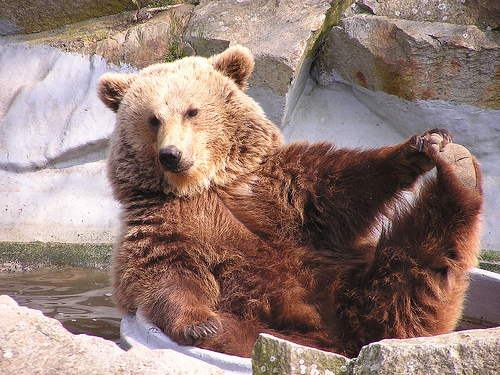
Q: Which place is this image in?
A: It is at the swimming pool.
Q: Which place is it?
A: It is a swimming pool.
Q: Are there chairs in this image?
A: No, there are no chairs.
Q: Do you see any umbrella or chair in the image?
A: No, there are no chairs or umbrellas.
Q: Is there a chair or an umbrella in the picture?
A: No, there are no chairs or umbrellas.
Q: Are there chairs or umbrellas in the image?
A: No, there are no chairs or umbrellas.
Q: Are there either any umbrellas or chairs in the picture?
A: No, there are no chairs or umbrellas.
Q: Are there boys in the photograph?
A: No, there are no boys.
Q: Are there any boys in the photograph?
A: No, there are no boys.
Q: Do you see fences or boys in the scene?
A: No, there are no boys or fences.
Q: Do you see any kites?
A: No, there are no kites.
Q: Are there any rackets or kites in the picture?
A: No, there are no kites or rackets.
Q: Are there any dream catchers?
A: No, there are no dream catchers.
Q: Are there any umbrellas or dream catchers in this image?
A: No, there are no dream catchers or umbrellas.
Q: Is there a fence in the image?
A: No, there are no fences.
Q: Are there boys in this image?
A: No, there are no boys.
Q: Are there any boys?
A: No, there are no boys.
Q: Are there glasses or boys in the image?
A: No, there are no boys or glasses.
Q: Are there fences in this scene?
A: No, there are no fences.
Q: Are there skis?
A: No, there are no skis.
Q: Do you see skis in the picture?
A: No, there are no skis.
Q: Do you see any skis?
A: No, there are no skis.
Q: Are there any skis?
A: No, there are no skis.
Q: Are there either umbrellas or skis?
A: No, there are no skis or umbrellas.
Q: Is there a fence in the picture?
A: No, there are no fences.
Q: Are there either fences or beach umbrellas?
A: No, there are no fences or beach umbrellas.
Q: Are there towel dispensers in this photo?
A: No, there are no towel dispensers.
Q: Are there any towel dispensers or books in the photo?
A: No, there are no towel dispensers or books.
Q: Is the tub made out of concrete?
A: Yes, the tub is made of concrete.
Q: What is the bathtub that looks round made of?
A: The bathtub is made of cement.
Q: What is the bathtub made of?
A: The bathtub is made of concrete.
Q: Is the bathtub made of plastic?
A: No, the bathtub is made of cement.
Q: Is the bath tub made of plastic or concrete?
A: The bath tub is made of concrete.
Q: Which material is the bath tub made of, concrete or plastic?
A: The bath tub is made of concrete.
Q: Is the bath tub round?
A: Yes, the bath tub is round.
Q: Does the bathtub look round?
A: Yes, the bathtub is round.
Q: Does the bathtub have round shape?
A: Yes, the bathtub is round.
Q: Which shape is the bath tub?
A: The bath tub is round.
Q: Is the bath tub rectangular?
A: No, the bath tub is round.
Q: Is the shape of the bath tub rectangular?
A: No, the bath tub is round.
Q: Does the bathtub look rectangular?
A: No, the bathtub is round.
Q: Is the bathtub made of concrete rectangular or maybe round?
A: The bath tub is round.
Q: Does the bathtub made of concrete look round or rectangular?
A: The bath tub is round.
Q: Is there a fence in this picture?
A: No, there are no fences.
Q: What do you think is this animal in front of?
A: The animal is in front of the water.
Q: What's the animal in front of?
A: The animal is in front of the water.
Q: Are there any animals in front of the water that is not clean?
A: Yes, there is an animal in front of the water.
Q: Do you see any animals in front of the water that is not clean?
A: Yes, there is an animal in front of the water.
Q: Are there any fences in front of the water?
A: No, there is an animal in front of the water.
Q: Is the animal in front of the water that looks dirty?
A: Yes, the animal is in front of the water.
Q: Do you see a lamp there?
A: No, there are no lamps.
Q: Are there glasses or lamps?
A: No, there are no lamps or glasses.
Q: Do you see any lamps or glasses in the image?
A: No, there are no lamps or glasses.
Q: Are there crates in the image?
A: No, there are no crates.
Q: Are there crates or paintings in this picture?
A: No, there are no crates or paintings.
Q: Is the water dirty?
A: Yes, the water is dirty.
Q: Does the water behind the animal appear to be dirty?
A: Yes, the water is dirty.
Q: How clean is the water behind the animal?
A: The water is dirty.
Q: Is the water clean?
A: No, the water is dirty.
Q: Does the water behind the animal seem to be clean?
A: No, the water is dirty.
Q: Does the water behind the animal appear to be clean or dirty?
A: The water is dirty.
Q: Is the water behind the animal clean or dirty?
A: The water is dirty.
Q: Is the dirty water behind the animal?
A: Yes, the water is behind the animal.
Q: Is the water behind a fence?
A: No, the water is behind the animal.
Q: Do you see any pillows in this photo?
A: No, there are no pillows.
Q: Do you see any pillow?
A: No, there are no pillows.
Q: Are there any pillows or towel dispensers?
A: No, there are no pillows or towel dispensers.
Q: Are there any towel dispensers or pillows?
A: No, there are no pillows or towel dispensers.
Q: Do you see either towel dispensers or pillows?
A: No, there are no pillows or towel dispensers.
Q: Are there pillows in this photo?
A: No, there are no pillows.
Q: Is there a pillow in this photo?
A: No, there are no pillows.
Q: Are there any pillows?
A: No, there are no pillows.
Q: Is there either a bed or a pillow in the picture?
A: No, there are no pillows or beds.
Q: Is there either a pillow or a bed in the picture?
A: No, there are no pillows or beds.